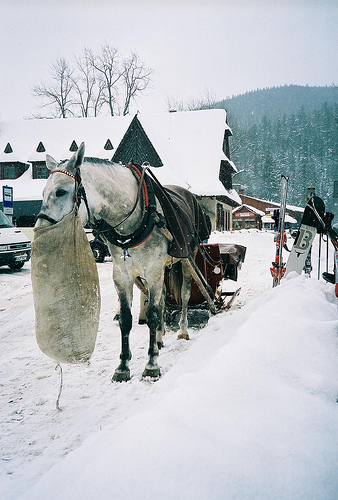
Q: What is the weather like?
A: Snowy.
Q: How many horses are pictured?
A: 1.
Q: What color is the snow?
A: White.